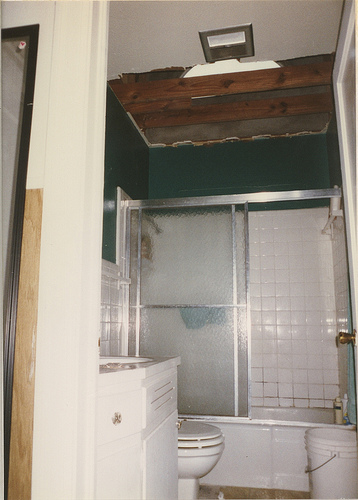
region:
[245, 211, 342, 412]
White tiles on the wall in the bath area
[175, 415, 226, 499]
A white toilet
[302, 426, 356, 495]
A white 5-gallon bucket with a handle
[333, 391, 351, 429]
Shower products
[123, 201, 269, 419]
Sliding glass doors for the bathtub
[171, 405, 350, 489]
A white bathtub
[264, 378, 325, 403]
White tiles with grout in the cracks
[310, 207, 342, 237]
A towel rack inside of the shower on the wall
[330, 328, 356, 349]
A golden colored doorknob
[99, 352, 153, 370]
A white sink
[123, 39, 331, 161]
a hole in the bathroom ceiling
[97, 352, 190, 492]
a white vanity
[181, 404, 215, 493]
a white toilet bowl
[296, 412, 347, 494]
a white bucket to catch the leaks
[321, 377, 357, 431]
bottles of shampoo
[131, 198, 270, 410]
translucent sliding glass shower doors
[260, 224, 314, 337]
white tile goes covers the wall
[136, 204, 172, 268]
brass shower head and dial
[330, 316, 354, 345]
a brass door knob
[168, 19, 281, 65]
a ceiling vent next to the hole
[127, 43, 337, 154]
the ceiling is broken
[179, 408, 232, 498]
the toilet seat is closed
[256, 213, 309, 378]
the walls are tiled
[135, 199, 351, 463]
the shower door is opne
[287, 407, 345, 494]
the pail in front of the toilet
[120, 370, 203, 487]
the cabinets are closed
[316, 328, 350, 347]
the door knob is gold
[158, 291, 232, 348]
the towel is hanging on the door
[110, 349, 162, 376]
the sink is white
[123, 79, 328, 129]
two bars of wood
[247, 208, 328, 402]
moldy white shower tile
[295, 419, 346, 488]
white bucket next to shower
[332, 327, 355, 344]
bathroom door knob gold colored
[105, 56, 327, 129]
ceiling joists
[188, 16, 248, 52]
bathroom cieling fan and light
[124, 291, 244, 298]
glass shower door handle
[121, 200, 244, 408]
obscure glass shower door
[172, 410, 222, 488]
toilet and toilet seat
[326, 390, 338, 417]
bottle of cleaning product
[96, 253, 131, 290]
towel bar no towels on it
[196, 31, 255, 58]
vent in the ceiling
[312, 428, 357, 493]
bucket on the floor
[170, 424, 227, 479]
white toilet with lid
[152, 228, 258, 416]
glass shower doors surround tub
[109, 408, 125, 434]
glass knobs on cabinet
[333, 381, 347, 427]
shampoo on the ledge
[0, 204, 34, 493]
wooden door frame in photo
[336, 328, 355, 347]
brass door knob on door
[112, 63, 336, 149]
ceiling is in repair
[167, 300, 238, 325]
blue towel in the shower